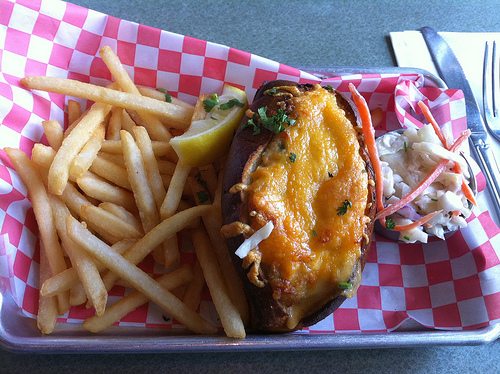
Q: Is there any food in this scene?
A: Yes, there is food.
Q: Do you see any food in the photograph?
A: Yes, there is food.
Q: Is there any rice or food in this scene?
A: Yes, there is food.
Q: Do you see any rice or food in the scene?
A: Yes, there is food.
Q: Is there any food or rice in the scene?
A: Yes, there is food.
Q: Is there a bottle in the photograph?
A: No, there are no bottles.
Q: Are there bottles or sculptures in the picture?
A: No, there are no bottles or sculptures.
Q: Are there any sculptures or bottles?
A: No, there are no bottles or sculptures.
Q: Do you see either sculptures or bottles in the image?
A: No, there are no bottles or sculptures.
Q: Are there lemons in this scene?
A: Yes, there is a lemon.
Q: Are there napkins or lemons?
A: Yes, there is a lemon.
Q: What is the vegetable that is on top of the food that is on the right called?
A: The vegetable is a lemon.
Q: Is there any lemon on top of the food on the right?
A: Yes, there is a lemon on top of the food.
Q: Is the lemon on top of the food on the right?
A: Yes, the lemon is on top of the food.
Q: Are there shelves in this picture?
A: No, there are no shelves.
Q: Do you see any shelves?
A: No, there are no shelves.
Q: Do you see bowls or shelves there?
A: No, there are no shelves or bowls.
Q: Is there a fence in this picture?
A: No, there are no fences.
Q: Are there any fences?
A: No, there are no fences.